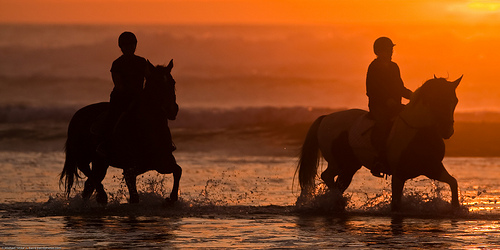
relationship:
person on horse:
[110, 33, 148, 118] [66, 58, 184, 208]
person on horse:
[368, 37, 412, 163] [304, 73, 462, 215]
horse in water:
[66, 58, 184, 208] [3, 80, 499, 246]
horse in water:
[304, 73, 462, 215] [3, 80, 499, 246]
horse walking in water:
[66, 58, 184, 208] [3, 80, 499, 246]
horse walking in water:
[304, 73, 462, 215] [3, 80, 499, 246]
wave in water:
[8, 98, 497, 161] [3, 80, 499, 246]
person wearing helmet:
[110, 33, 148, 118] [117, 32, 138, 47]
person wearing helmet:
[368, 37, 412, 163] [374, 35, 393, 55]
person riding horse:
[110, 33, 148, 118] [66, 58, 184, 208]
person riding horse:
[368, 37, 412, 163] [304, 73, 462, 215]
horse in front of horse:
[304, 73, 462, 215] [66, 58, 184, 208]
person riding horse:
[368, 37, 412, 163] [66, 58, 184, 208]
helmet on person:
[117, 32, 138, 47] [110, 33, 148, 118]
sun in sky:
[443, 6, 495, 30] [4, 2, 497, 110]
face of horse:
[152, 66, 184, 121] [66, 58, 184, 208]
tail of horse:
[64, 122, 78, 190] [66, 58, 184, 208]